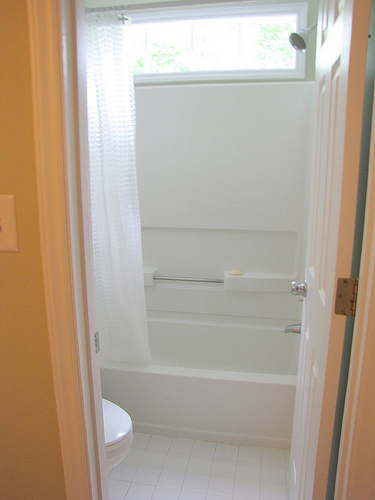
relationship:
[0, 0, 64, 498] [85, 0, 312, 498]
wall outside bathroom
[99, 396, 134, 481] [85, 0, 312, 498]
toilet in bathroom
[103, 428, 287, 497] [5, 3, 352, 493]
floor to bathroom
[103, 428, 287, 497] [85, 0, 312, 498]
floor in bathroom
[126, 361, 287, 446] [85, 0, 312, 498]
tub wall in bathroom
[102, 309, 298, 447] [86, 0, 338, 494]
bathtub in bathroom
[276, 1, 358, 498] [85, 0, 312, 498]
door of bathroom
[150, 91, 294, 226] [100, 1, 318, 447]
white wall in shower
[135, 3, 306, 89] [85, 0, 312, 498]
window in bathroom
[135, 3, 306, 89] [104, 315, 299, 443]
window above tub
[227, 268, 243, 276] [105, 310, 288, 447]
soap in tub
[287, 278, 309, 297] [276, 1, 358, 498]
knob of door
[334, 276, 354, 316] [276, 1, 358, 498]
hinge in door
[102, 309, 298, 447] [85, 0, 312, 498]
bathtub in bathroom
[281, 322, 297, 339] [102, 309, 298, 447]
faucet of bathtub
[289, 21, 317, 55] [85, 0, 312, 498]
shower head of bathroom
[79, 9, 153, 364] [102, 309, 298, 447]
white curtain of bathtub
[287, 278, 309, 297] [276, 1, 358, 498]
knob to door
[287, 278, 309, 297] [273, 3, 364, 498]
knob of door